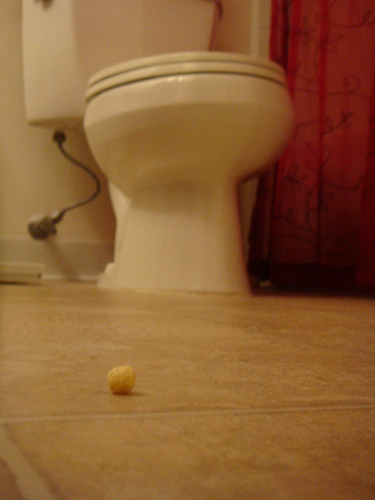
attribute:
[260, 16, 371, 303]
curtain — red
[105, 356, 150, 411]
corn puff — singular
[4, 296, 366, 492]
floor — brown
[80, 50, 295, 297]
toilet seat — cream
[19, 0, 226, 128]
toilet tank — cream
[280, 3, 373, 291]
curtain — red, embroidered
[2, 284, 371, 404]
linoleum flooring — tan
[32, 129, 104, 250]
pipe — small, grey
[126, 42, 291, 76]
toilet lead — cream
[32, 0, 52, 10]
handle — chrome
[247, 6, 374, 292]
curtain — red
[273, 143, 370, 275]
flowers — black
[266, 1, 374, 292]
curtain — red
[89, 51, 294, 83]
lid — closed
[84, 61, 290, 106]
seat — closed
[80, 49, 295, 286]
toilet — white, porcelain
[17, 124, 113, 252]
plumbing — toilet's plumbing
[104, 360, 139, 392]
ball — yellow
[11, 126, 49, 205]
wall — beige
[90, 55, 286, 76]
lid — toilet lid, down